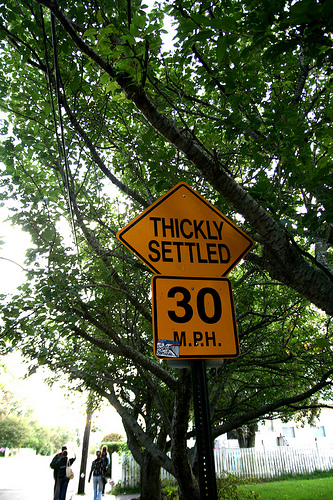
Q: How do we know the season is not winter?
A: There are leaves on the trees.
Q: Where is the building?
A: Behind the fence.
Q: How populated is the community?
A: Thickly settled.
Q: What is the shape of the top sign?
A: Diamond.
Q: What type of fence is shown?
A: Picket.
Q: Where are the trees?
A: Behind the sign.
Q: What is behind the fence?
A: Building.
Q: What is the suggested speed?
A: 30 mph.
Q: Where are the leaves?
A: On the tree.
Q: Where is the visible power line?
A: In the tree.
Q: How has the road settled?
A: Thickly.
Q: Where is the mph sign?
A: On a post.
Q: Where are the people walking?
A: On the sidewalk.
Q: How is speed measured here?
A: Miles per hour.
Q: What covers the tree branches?
A: Leaves.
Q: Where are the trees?
A: Behind the sign.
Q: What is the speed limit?
A: 30 mph.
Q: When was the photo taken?
A: Daytime.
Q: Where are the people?
A: On the sidewalk.